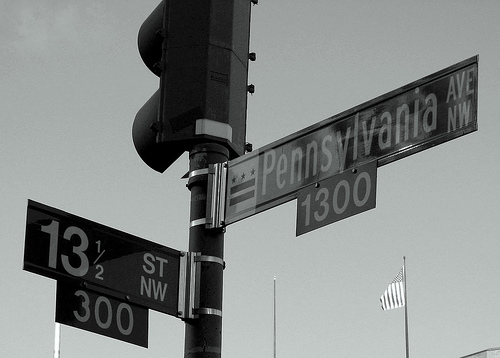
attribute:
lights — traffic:
[118, 4, 256, 172]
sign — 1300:
[284, 169, 387, 228]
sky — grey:
[7, 5, 487, 355]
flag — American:
[373, 261, 410, 314]